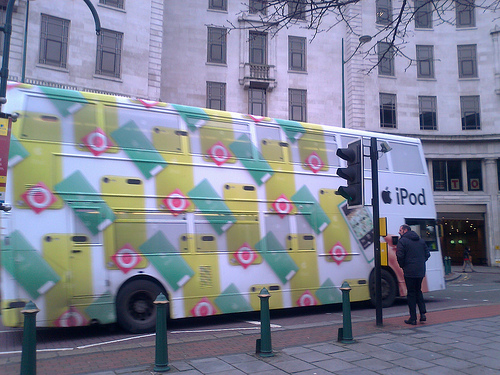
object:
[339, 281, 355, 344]
post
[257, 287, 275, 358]
post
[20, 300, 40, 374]
post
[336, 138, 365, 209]
sign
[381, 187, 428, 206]
ipod logo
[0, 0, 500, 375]
outside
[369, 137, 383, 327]
pole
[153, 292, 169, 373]
pillars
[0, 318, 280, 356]
line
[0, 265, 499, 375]
gray road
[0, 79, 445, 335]
bus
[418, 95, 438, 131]
window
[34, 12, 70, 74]
window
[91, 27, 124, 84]
window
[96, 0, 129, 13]
window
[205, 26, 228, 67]
window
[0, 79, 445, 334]
artwork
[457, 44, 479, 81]
window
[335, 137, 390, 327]
traffic signal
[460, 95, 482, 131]
window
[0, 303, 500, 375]
concrete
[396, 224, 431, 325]
man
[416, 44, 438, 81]
window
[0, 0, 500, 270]
building